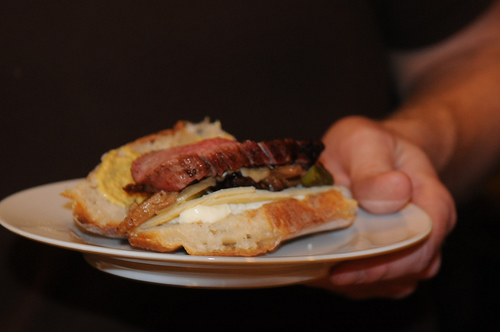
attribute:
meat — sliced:
[135, 165, 190, 192]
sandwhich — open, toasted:
[109, 97, 308, 235]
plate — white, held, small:
[12, 187, 79, 254]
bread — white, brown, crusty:
[48, 183, 113, 236]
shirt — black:
[383, 9, 436, 47]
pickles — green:
[299, 159, 330, 193]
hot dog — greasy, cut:
[229, 136, 278, 160]